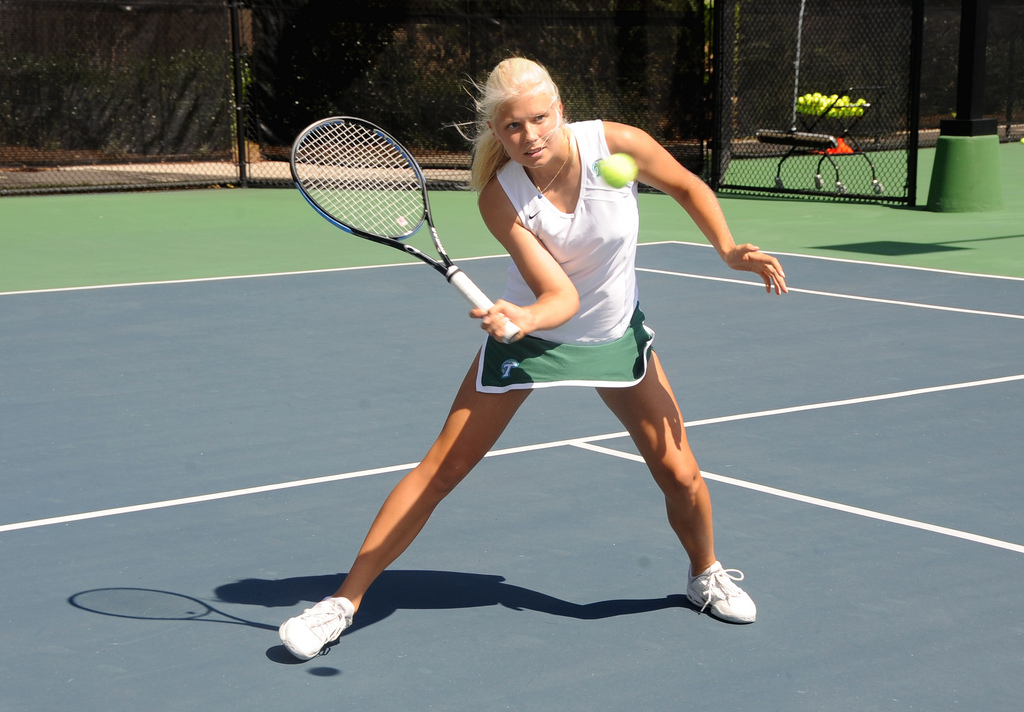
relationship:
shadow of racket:
[67, 584, 281, 632] [287, 115, 519, 345]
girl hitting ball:
[277, 53, 790, 664] [598, 151, 640, 191]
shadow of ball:
[306, 664, 340, 678] [599, 153, 638, 189]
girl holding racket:
[277, 53, 778, 663] [287, 115, 522, 345]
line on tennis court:
[630, 263, 1022, 319] [1, 133, 1020, 710]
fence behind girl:
[233, 1, 719, 191] [277, 53, 778, 663]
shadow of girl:
[209, 570, 711, 662] [277, 53, 778, 663]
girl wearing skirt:
[277, 53, 778, 663] [476, 301, 656, 393]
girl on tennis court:
[277, 53, 778, 663] [1, 133, 1020, 710]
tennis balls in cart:
[794, 91, 872, 121] [756, 81, 888, 199]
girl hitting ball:
[277, 53, 778, 663] [599, 153, 638, 189]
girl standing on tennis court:
[277, 53, 778, 663] [1, 133, 1020, 710]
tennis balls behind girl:
[794, 91, 872, 121] [277, 53, 778, 663]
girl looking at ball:
[277, 53, 778, 663] [599, 153, 638, 189]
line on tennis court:
[568, 440, 1022, 558] [1, 133, 1020, 710]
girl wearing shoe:
[277, 53, 778, 663] [277, 596, 356, 660]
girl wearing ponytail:
[277, 53, 778, 663] [468, 125, 502, 193]